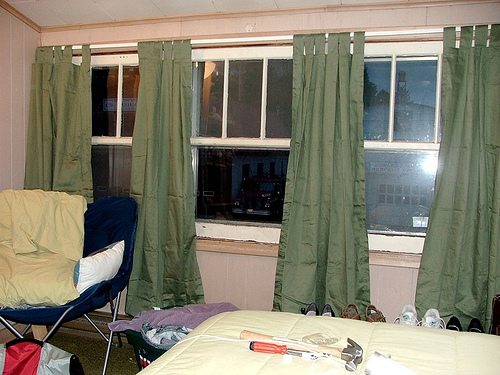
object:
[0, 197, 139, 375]
chairs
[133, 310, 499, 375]
bed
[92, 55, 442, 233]
panes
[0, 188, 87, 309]
pillow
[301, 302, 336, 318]
shoes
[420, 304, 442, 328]
white shoe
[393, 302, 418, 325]
white shoe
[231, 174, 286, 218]
car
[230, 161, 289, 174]
wall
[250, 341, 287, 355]
redhandle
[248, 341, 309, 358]
chissel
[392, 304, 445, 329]
shoes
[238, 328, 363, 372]
hammer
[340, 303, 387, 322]
shoes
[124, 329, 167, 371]
laundry basket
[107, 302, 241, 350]
clothes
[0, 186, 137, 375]
seat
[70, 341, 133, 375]
floor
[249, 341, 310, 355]
screwdriver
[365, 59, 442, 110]
sky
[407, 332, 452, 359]
bed sheet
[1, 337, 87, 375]
bag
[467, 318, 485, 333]
black shoe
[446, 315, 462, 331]
black shoe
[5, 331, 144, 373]
carpeting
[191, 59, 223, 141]
window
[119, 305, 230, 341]
towel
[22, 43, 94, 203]
curtain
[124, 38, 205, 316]
curtain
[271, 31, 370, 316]
curtain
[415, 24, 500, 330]
curtain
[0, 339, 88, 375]
duffel bag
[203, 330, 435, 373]
comforter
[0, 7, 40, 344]
wall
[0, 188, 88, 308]
blanket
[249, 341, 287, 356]
hand